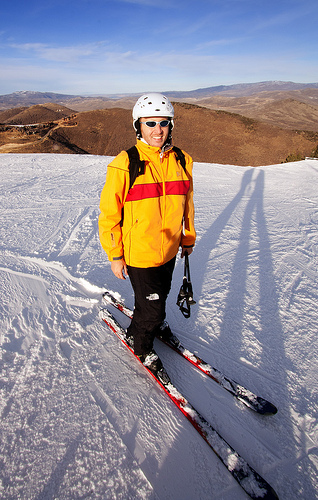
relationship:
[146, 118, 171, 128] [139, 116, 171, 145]
sunglasses on face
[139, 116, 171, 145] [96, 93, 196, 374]
face of man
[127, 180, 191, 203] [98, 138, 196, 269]
stripe on jacket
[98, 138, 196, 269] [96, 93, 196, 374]
jacket of man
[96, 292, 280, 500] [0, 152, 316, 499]
skis on snow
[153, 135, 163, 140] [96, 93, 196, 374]
smile on man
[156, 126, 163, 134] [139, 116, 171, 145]
nose on face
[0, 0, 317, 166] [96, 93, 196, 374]
mountains behind man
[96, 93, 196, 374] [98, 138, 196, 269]
man wearing jacket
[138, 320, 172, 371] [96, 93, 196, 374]
boots of man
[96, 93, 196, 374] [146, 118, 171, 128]
man wearing sunglasses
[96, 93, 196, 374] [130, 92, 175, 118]
man wearing helmet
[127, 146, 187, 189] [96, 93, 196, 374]
straps on man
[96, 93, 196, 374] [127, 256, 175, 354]
man wearing pants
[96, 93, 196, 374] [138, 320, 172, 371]
man wearing boots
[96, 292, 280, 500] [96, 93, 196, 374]
skis on man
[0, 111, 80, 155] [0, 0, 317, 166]
path on mountains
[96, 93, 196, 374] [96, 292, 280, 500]
man on skis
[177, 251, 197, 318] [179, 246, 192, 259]
poles in hand